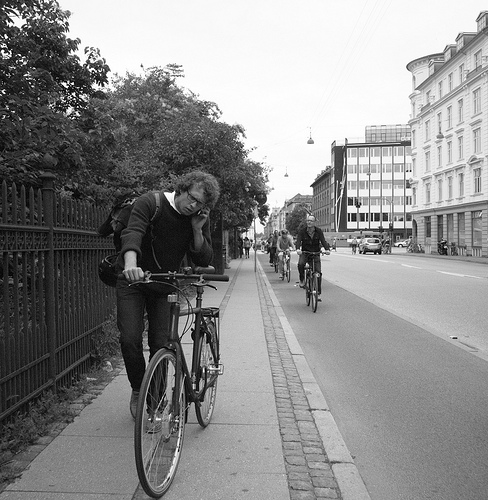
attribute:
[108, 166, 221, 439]
man — wearing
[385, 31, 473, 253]
building — light colored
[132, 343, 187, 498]
wheel — black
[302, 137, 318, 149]
object — hanging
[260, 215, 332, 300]
riders — bike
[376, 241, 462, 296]
line — dividing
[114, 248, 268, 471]
bike — handle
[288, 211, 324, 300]
rider — bike, in lead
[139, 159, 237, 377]
man — holding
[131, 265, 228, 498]
bike — dark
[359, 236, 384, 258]
car — rear facing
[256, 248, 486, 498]
street — city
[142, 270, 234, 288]
bars — straight